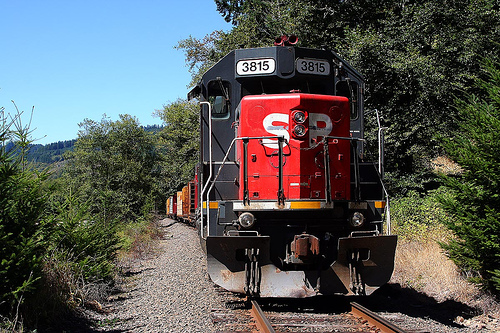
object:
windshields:
[211, 80, 357, 119]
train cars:
[165, 172, 197, 221]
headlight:
[349, 211, 364, 228]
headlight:
[239, 212, 258, 228]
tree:
[63, 113, 172, 214]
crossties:
[203, 235, 399, 300]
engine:
[187, 32, 399, 297]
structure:
[236, 92, 352, 202]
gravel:
[81, 215, 500, 333]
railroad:
[246, 300, 404, 333]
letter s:
[261, 112, 290, 149]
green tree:
[431, 36, 500, 300]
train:
[164, 33, 398, 299]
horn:
[273, 34, 299, 46]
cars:
[157, 172, 211, 228]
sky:
[2, 0, 239, 145]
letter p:
[308, 113, 333, 147]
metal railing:
[237, 135, 362, 207]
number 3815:
[301, 60, 325, 72]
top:
[234, 46, 333, 78]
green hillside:
[0, 124, 169, 166]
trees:
[210, 0, 497, 73]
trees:
[429, 47, 499, 295]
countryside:
[2, 2, 498, 331]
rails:
[231, 298, 406, 332]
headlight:
[290, 110, 308, 138]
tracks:
[228, 293, 401, 329]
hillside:
[37, 207, 497, 327]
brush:
[394, 191, 443, 240]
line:
[158, 153, 209, 230]